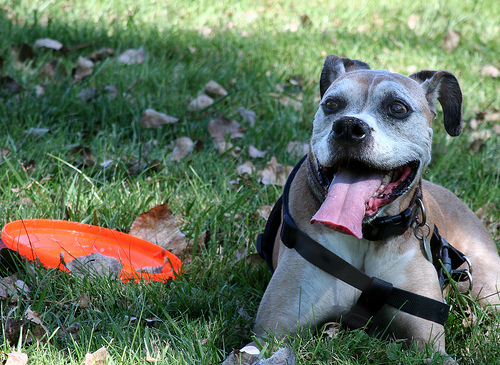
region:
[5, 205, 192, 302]
the frisbee in the grass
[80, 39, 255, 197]
leaves on the grass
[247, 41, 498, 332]
dog on the grass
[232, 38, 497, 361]
the dog is laying down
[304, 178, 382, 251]
tongue of the dog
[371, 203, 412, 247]
collar on the dog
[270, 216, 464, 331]
harness on the dog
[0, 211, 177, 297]
the frisbee is orange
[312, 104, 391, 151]
nose of the dog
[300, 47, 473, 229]
the head of the dog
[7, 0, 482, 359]
Photo taken during the day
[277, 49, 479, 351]
Dog lying in the grass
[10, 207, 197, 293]
Orange frisbee in the grass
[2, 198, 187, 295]
Frisbee on the ground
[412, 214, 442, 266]
Tags on the dog's collar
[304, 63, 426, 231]
Gray fur on the dog's face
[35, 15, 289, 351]
Leaves in the grass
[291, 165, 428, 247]
Collar on the dog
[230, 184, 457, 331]
Black harness on the dog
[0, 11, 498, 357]
No people in the photo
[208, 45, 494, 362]
a dog sticking out his tongue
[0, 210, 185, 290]
a frisbee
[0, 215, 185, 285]
an orange frisbee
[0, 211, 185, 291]
a frisbee on the ground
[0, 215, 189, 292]
an orange frisbee on the ground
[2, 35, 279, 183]
dried leaves on the grass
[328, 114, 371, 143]
black nose of the dog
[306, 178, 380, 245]
a tongue of the dog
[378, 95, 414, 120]
an eye of the dog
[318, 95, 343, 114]
an eye of the dog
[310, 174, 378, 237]
dog's tongue is hanging out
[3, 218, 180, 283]
orange frisbee on the ground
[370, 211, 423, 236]
black collar on the dog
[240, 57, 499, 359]
dog laying down on the grass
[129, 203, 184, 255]
brown leaf on the grass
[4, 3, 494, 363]
green grass with brown leaves on the ground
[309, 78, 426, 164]
dog's face is white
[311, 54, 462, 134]
dog's ears are back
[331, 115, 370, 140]
dog's nose is black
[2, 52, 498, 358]
dog is laying by the frisbee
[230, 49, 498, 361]
A dog sitting on the grass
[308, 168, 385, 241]
The tongue of a dog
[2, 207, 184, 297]
Frisbee on the grass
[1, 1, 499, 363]
Leaves are on the grass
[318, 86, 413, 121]
A pair of dog eyes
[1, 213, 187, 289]
A frisbee is orange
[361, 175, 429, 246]
Collar around the dog's neck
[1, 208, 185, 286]
A frisbee is round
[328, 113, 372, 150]
Black nose of a dog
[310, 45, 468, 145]
Two ears of a dog